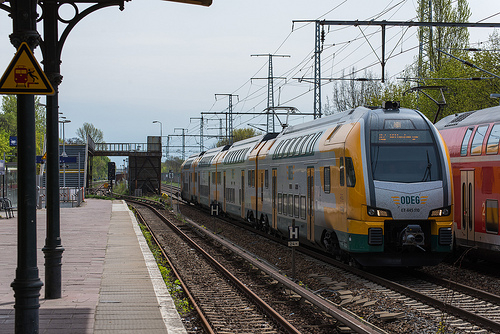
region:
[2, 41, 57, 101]
Triangle sign is yellow and black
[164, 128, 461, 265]
Yellow and grey train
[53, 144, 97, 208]
Steps coming down to platform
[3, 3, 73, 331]
Black pole holding yellow sign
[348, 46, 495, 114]
Trees beside the red train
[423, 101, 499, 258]
Red train next to yellow train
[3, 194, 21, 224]
Black bench on the platform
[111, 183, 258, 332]
Tracks without a train on them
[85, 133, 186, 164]
Bridge over train tracks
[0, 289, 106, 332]
Shadow on the platform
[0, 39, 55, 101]
yellow triangle sign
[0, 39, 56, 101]
yellow triangle sign with a train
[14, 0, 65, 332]
two black large poles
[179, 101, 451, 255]
yellow and grey large train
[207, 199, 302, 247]
two black H signs on the rails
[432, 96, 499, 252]
part of a red train in the right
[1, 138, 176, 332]
train station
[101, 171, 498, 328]
black rails in the floor in train station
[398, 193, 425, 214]
ODEG letters in front of a yellow and grey train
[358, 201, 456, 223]
two front lights on a yellow and grey train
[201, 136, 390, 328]
the railroads are rusty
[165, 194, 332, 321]
the railroads are rusty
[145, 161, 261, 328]
the railroads are rusty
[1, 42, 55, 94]
a sign shaped like a triangle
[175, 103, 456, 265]
a long train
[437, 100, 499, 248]
a short red train car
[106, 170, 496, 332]
a long piece of railroad tracks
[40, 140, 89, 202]
stairs that lead up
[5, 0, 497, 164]
an overcast sky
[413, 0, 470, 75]
a tall green leafy tree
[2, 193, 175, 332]
an empty train platform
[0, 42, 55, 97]
a sign hanging on a pole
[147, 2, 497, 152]
many wires above the trains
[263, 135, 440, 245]
yellow white and black car of train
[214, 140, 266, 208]
yellow white and black car of train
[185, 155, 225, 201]
yellow white and black car of train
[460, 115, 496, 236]
red and black car of train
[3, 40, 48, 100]
black yellow and red caution sign on post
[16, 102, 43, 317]
black metal post in train station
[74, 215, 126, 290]
brown and tan pavement on train platform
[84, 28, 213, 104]
white clouds against blue sky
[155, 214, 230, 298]
brown tracks near train platform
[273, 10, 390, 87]
posts and wires in train station